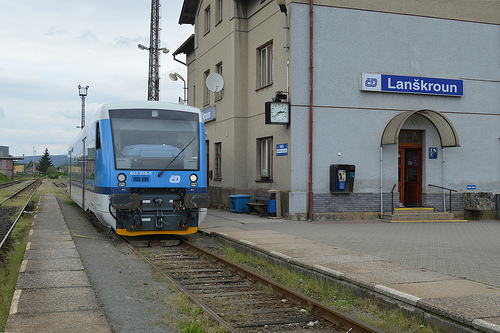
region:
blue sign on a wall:
[360, 69, 465, 98]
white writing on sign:
[383, 75, 470, 98]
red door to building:
[395, 129, 424, 208]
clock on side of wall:
[263, 98, 295, 128]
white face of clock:
[271, 105, 288, 118]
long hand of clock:
[275, 111, 280, 117]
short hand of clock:
[274, 108, 284, 115]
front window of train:
[111, 112, 200, 173]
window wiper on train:
[152, 133, 207, 180]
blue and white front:
[92, 99, 209, 201]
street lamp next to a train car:
[68, 77, 98, 227]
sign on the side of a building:
[337, 59, 470, 105]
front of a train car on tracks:
[101, 99, 242, 306]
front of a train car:
[106, 104, 212, 247]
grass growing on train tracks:
[115, 252, 303, 319]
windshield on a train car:
[101, 102, 201, 169]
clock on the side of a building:
[260, 92, 309, 250]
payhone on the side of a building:
[321, 148, 368, 230]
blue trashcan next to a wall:
[211, 177, 255, 222]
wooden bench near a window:
[244, 132, 273, 224]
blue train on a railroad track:
[61, 98, 206, 246]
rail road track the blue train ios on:
[134, 236, 397, 331]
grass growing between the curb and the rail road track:
[198, 226, 413, 331]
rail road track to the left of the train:
[0, 171, 39, 266]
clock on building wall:
[258, 86, 290, 123]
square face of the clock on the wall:
[269, 103, 289, 118]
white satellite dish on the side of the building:
[203, 68, 225, 99]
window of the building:
[251, 40, 276, 89]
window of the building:
[248, 138, 271, 177]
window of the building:
[213, 143, 220, 175]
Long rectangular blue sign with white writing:
[356, 68, 466, 104]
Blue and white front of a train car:
[97, 102, 211, 192]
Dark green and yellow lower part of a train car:
[109, 193, 204, 239]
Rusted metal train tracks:
[169, 246, 243, 326]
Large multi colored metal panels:
[254, 232, 369, 284]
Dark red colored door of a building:
[396, 128, 428, 213]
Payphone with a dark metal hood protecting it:
[326, 162, 358, 194]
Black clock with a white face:
[261, 95, 294, 129]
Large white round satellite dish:
[203, 64, 223, 96]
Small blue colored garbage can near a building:
[227, 183, 248, 215]